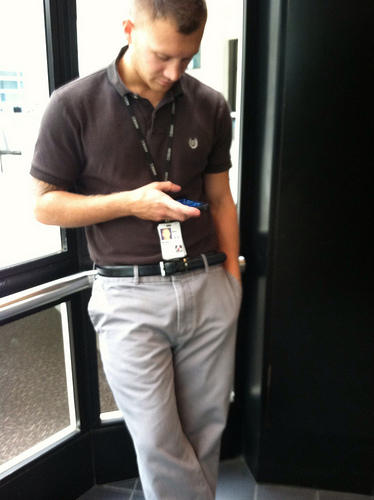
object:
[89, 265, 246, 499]
khakies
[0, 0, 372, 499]
building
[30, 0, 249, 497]
man standing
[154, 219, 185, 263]
lanyard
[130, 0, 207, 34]
brown hair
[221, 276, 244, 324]
pocket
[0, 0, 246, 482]
glass pane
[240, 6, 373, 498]
walls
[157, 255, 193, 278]
buckle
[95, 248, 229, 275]
belt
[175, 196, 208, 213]
cell phone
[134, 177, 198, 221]
hand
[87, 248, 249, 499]
pants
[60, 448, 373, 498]
floor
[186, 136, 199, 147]
logo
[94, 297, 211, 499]
leg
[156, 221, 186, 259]
badge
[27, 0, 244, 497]
boy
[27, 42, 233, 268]
polo shirt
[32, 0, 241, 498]
man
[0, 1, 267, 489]
window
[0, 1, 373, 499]
inside